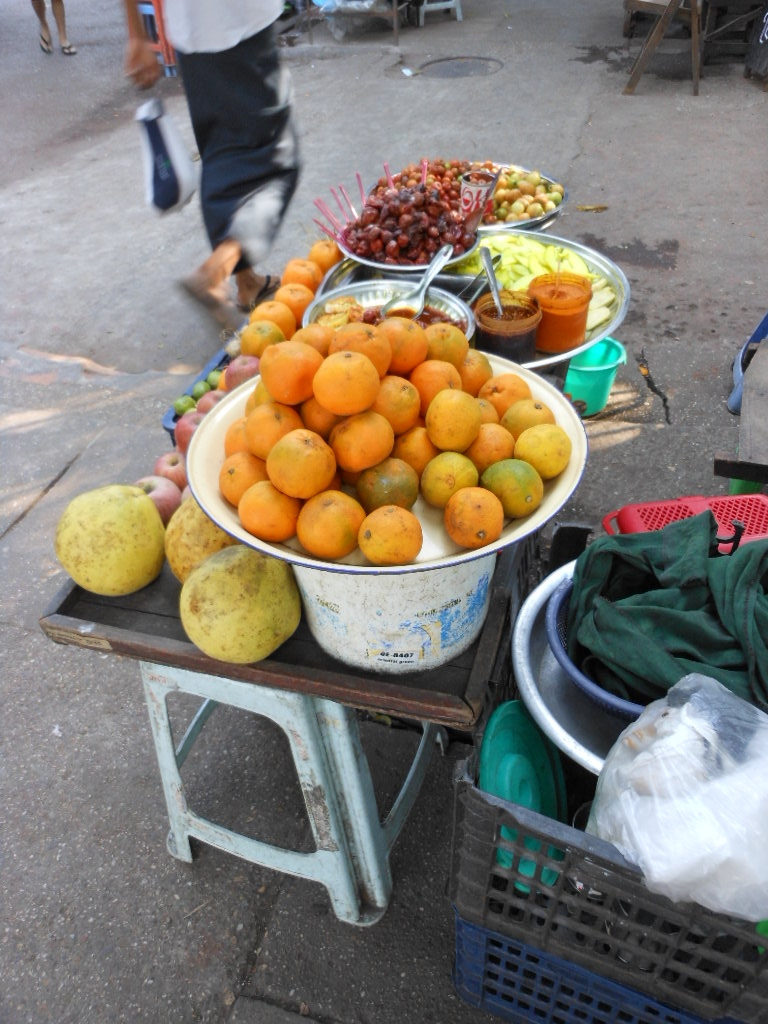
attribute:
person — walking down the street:
[126, 1, 324, 319]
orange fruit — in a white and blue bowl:
[217, 305, 574, 561]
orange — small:
[361, 496, 425, 570]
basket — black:
[444, 751, 766, 1021]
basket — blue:
[446, 912, 687, 1022]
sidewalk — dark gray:
[6, 6, 767, 1022]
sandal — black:
[178, 273, 243, 333]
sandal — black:
[231, 272, 279, 311]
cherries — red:
[366, 192, 479, 245]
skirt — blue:
[178, 62, 303, 208]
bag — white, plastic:
[580, 668, 744, 923]